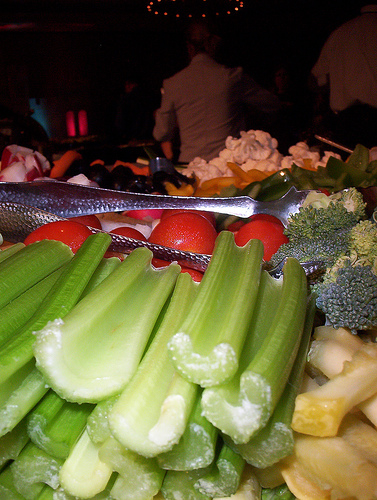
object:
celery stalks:
[0, 230, 316, 498]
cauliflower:
[183, 131, 340, 183]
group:
[91, 1, 375, 166]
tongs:
[7, 176, 350, 283]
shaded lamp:
[65, 105, 90, 142]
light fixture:
[147, 0, 243, 17]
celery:
[0, 230, 319, 498]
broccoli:
[271, 190, 377, 332]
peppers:
[214, 143, 377, 213]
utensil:
[0, 180, 334, 280]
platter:
[0, 134, 377, 499]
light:
[65, 104, 89, 138]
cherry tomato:
[25, 200, 288, 281]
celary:
[0, 231, 319, 496]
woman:
[152, 23, 290, 165]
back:
[153, 64, 243, 166]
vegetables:
[0, 132, 377, 500]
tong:
[1, 179, 327, 280]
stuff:
[223, 398, 272, 444]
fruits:
[9, 137, 364, 255]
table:
[0, 151, 377, 500]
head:
[276, 187, 376, 329]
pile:
[21, 210, 288, 268]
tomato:
[0, 209, 291, 280]